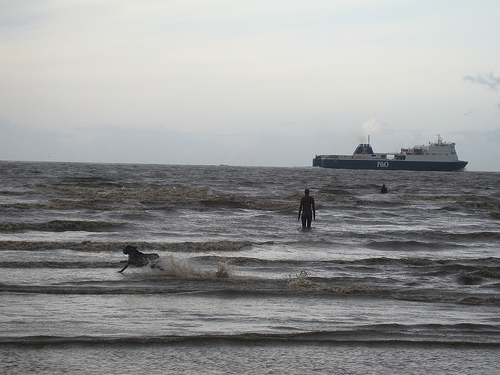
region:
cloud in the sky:
[464, 61, 495, 99]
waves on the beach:
[196, 240, 473, 372]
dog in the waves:
[113, 227, 164, 282]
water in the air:
[165, 250, 205, 285]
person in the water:
[288, 183, 320, 250]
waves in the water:
[370, 220, 483, 252]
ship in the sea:
[284, 127, 481, 180]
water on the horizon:
[48, 150, 237, 174]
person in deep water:
[369, 179, 394, 199]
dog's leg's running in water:
[111, 255, 137, 281]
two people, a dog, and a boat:
[118, 132, 466, 272]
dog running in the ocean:
[111, 236, 178, 279]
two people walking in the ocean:
[298, 181, 390, 230]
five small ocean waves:
[6, 163, 110, 366]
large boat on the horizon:
[311, 132, 470, 174]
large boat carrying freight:
[313, 133, 469, 172]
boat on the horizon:
[213, 161, 233, 169]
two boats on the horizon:
[204, 130, 481, 174]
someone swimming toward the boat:
[370, 181, 401, 201]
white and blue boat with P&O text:
[304, 128, 473, 175]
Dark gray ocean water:
[233, 236, 258, 256]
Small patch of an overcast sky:
[183, 35, 233, 70]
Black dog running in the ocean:
[121, 242, 165, 280]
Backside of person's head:
[303, 188, 310, 194]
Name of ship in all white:
[371, 160, 393, 171]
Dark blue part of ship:
[412, 162, 425, 170]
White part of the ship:
[426, 154, 433, 160]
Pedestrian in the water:
[374, 182, 393, 196]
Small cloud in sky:
[461, 67, 499, 94]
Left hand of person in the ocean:
[297, 207, 304, 220]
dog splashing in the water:
[111, 240, 237, 282]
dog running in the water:
[86, 239, 197, 278]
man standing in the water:
[291, 172, 324, 237]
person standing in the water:
[286, 177, 328, 240]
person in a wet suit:
[286, 174, 326, 256]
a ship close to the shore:
[301, 133, 474, 185]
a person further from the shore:
[362, 176, 393, 216]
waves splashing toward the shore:
[9, 225, 415, 360]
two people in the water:
[279, 172, 402, 240]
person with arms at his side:
[283, 181, 323, 235]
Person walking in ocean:
[292, 186, 319, 230]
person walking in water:
[293, 181, 320, 231]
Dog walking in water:
[111, 236, 168, 283]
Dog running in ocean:
[121, 237, 168, 278]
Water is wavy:
[2, 168, 498, 346]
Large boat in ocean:
[307, 131, 469, 173]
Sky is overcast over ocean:
[3, 8, 494, 164]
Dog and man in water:
[111, 183, 319, 279]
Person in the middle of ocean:
[375, 175, 391, 193]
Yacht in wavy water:
[311, 133, 469, 176]